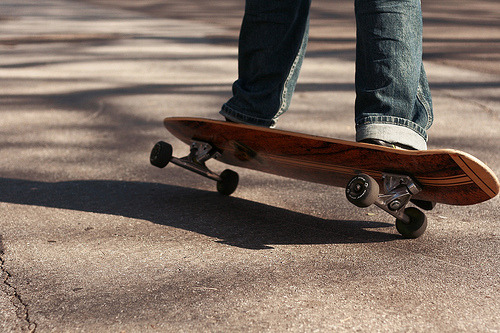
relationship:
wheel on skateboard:
[150, 141, 173, 167] [160, 116, 500, 214]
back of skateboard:
[175, 125, 483, 201] [160, 116, 500, 214]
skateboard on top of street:
[160, 116, 500, 214] [3, 5, 491, 332]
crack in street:
[1, 253, 34, 332] [3, 5, 491, 332]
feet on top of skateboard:
[364, 134, 416, 161] [160, 116, 500, 214]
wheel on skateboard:
[215, 171, 238, 192] [160, 116, 500, 214]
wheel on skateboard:
[349, 174, 374, 203] [160, 116, 500, 214]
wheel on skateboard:
[400, 208, 427, 238] [160, 116, 500, 214]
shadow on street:
[4, 177, 402, 246] [3, 5, 491, 332]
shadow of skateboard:
[4, 177, 402, 246] [160, 116, 500, 214]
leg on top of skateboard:
[354, 2, 432, 157] [160, 116, 500, 214]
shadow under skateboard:
[4, 177, 402, 246] [160, 116, 500, 214]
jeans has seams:
[243, 2, 434, 156] [357, 114, 434, 141]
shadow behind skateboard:
[4, 177, 402, 246] [160, 116, 500, 214]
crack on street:
[1, 253, 34, 332] [3, 5, 491, 332]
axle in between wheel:
[174, 138, 220, 186] [150, 141, 173, 167]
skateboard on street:
[160, 116, 500, 214] [3, 5, 491, 332]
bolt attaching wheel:
[353, 183, 363, 190] [349, 174, 374, 203]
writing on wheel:
[356, 177, 370, 186] [349, 174, 374, 203]